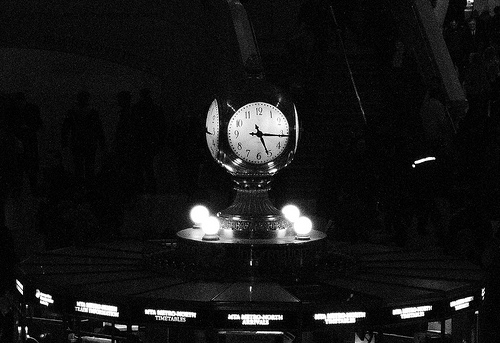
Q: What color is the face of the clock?
A: White.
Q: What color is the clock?
A: Silver.